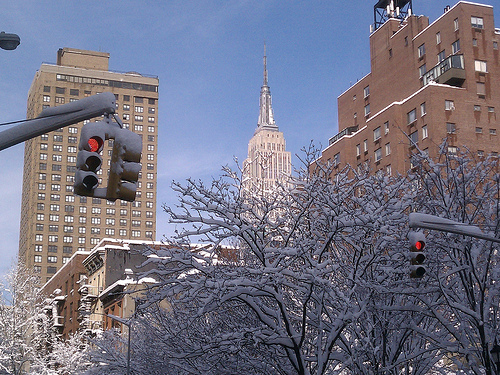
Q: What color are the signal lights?
A: Red.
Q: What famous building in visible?
A: Empire State Building.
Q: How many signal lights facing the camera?
A: 2.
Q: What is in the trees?
A: Snow.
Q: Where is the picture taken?
A: Street.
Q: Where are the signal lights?
A: On poles.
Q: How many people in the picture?
A: Zero.